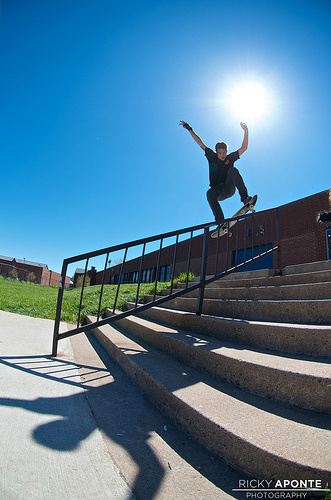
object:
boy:
[177, 118, 252, 226]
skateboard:
[209, 191, 258, 241]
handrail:
[52, 206, 286, 358]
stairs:
[83, 309, 331, 499]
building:
[92, 186, 331, 285]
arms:
[178, 117, 213, 161]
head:
[215, 141, 227, 164]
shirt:
[202, 147, 240, 185]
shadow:
[0, 286, 253, 500]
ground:
[0, 271, 327, 498]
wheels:
[249, 202, 255, 212]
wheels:
[223, 223, 229, 235]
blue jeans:
[205, 165, 249, 223]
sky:
[0, 0, 330, 275]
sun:
[219, 71, 281, 129]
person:
[178, 118, 252, 226]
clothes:
[201, 149, 250, 225]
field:
[0, 270, 200, 326]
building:
[0, 252, 75, 288]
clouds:
[39, 232, 62, 259]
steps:
[84, 304, 330, 412]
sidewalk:
[0, 306, 258, 499]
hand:
[178, 117, 189, 131]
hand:
[239, 119, 251, 132]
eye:
[217, 149, 222, 154]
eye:
[222, 147, 227, 155]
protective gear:
[183, 120, 194, 133]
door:
[232, 240, 273, 270]